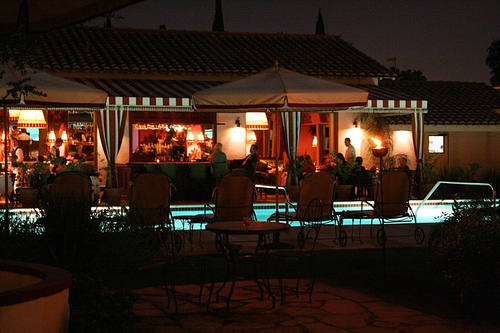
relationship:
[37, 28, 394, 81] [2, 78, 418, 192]
roof on building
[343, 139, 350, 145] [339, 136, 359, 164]
face on man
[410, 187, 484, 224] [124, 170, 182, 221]
pool in front of chair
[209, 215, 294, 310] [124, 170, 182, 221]
table behind chair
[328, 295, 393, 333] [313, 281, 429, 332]
shadow on ground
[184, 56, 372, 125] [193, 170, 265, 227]
umbrella on chair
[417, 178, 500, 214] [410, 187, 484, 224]
rail on pool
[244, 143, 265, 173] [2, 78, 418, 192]
person in building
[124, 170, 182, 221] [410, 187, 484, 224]
chair by pool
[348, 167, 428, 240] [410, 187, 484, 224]
chair by pool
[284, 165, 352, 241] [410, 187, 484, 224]
chair by pool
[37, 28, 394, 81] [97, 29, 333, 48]
roof on top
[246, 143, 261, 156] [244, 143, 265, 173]
head on man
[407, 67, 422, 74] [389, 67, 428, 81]
leaf on tree